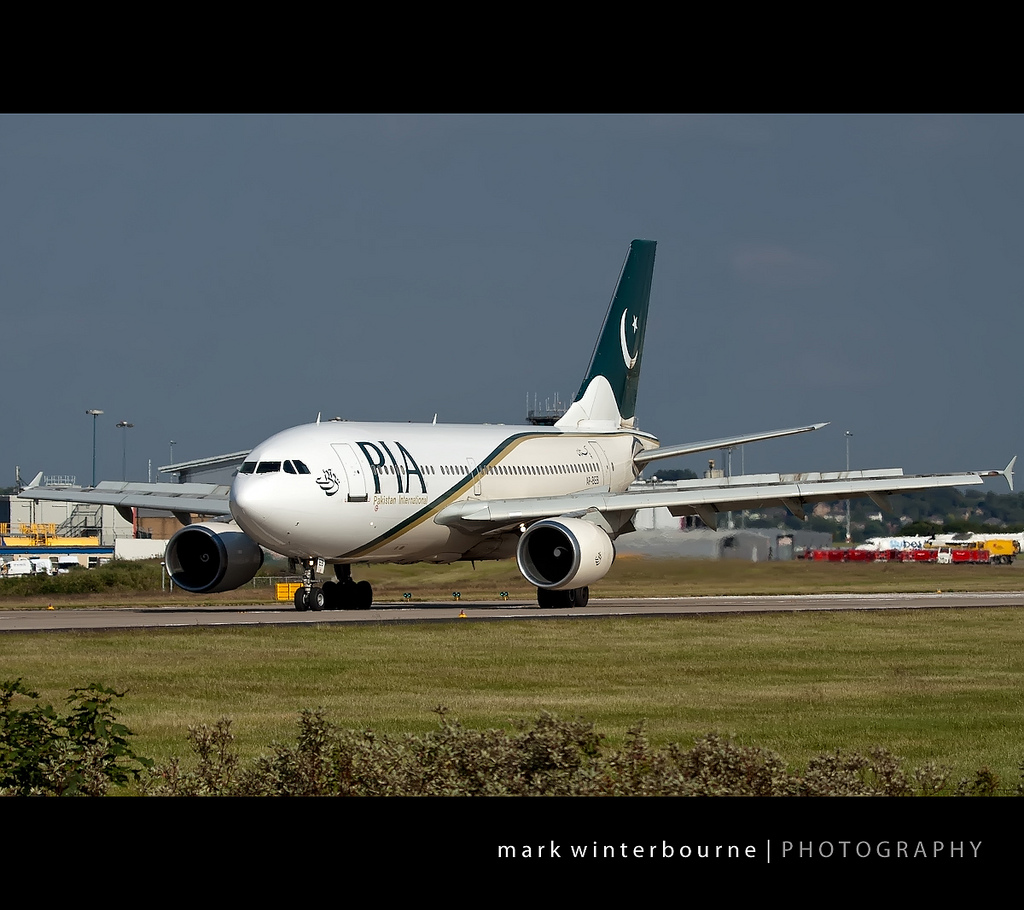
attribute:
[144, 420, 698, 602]
airplane — large, passenger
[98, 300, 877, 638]
plane — commercial, taking off, white, large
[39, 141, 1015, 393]
sky — grey, blue, clear, dark, gray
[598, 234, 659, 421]
tail — green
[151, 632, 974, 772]
grass — green, brown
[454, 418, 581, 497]
stripes — green, yellow, slanted, painted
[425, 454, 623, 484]
windows — passenger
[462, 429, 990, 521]
wings — small, large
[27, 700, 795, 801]
bushes — green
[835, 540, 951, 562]
carriers — red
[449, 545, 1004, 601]
field — grassy, green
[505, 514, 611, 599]
engine — large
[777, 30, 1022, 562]
trucks — maintenance, yellow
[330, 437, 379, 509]
door — closed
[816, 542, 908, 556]
containers — red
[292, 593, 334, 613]
wheels — black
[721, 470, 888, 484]
air vent — silver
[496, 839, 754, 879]
name — photographer